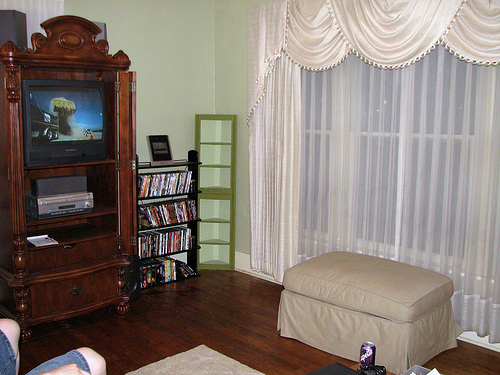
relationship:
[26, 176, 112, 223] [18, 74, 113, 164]
sound system for television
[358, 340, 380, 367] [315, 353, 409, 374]
soda on table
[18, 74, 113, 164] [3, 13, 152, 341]
television in entertainment center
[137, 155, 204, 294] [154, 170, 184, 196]
dvd rack filled with dvds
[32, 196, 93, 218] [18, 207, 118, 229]
dvd player on shelf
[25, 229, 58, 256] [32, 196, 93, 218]
booklet for dvd player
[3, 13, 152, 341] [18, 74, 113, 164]
entertainment center for television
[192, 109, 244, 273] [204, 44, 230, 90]
rack in corner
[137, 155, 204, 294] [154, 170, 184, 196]
dvd rack for dvds